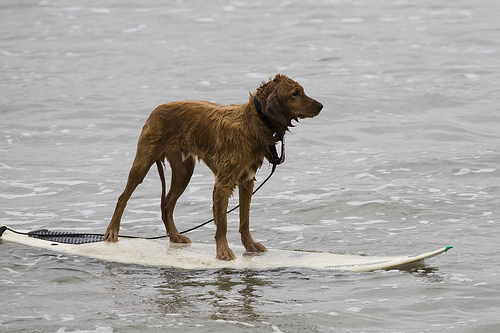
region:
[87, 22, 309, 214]
the dog is brown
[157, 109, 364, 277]
the dog is on a surfboard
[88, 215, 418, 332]
the surfboard is long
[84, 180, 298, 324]
the water is calm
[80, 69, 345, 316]
this is in the ocean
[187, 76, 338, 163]
the dog is wet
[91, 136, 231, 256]
the dog has four legs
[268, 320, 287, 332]
foam in the water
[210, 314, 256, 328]
foam in the water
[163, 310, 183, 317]
foam in the water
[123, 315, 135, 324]
foam in the water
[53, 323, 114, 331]
foam in the water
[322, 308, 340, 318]
foam in the water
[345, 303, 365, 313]
foam in the water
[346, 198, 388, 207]
foam in the water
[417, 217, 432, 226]
foam in the water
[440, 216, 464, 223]
foam in the water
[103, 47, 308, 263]
dog on the surfboard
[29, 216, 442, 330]
the surfboard is white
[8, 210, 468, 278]
the surfboard is white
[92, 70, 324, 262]
A brown dog on a surfboard.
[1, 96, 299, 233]
A surfboard connected to a dog.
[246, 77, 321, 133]
The head of a wet dog.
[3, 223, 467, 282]
A white surfboard on water.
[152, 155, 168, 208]
A wet tail of a dog.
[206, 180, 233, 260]
A right front dog leg.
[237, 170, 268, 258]
A left front dog leg.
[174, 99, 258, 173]
Torso of a brown dog.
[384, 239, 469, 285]
The tip of a surfboard.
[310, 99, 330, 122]
The nose of a brown dog.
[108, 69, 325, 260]
a dog on a surf board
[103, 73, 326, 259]
a dog on a leash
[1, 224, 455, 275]
a surfboard in the water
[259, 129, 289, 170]
the clip on part of a leash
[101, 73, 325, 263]
a wet brown dog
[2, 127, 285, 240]
a leash attatched between a dog and surfboard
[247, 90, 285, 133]
a black dog colar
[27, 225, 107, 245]
a black panel on a surf board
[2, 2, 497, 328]
a surfboard in smooth water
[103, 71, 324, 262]
a dog looking out from a surfboard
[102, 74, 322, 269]
a dog on a surfboard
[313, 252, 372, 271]
a surfboard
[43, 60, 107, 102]
the water